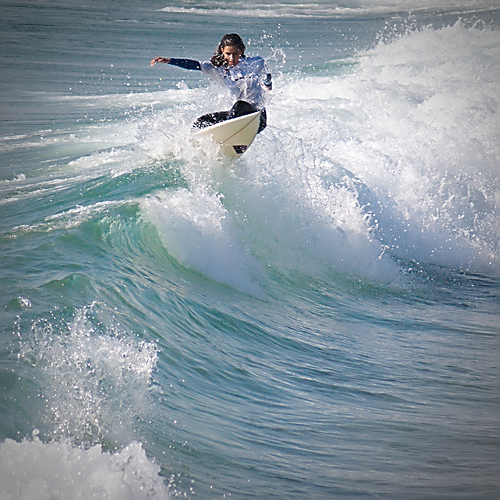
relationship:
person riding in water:
[151, 26, 282, 124] [4, 5, 494, 497]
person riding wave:
[151, 26, 282, 124] [166, 7, 497, 285]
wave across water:
[166, 7, 497, 285] [4, 5, 494, 497]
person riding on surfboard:
[151, 26, 282, 124] [187, 107, 268, 175]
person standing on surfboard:
[151, 26, 282, 124] [187, 107, 268, 175]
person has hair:
[151, 26, 282, 124] [205, 32, 245, 66]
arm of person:
[147, 54, 217, 81] [151, 26, 282, 124]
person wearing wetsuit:
[151, 26, 282, 124] [168, 56, 282, 154]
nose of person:
[229, 52, 234, 62] [151, 26, 282, 124]